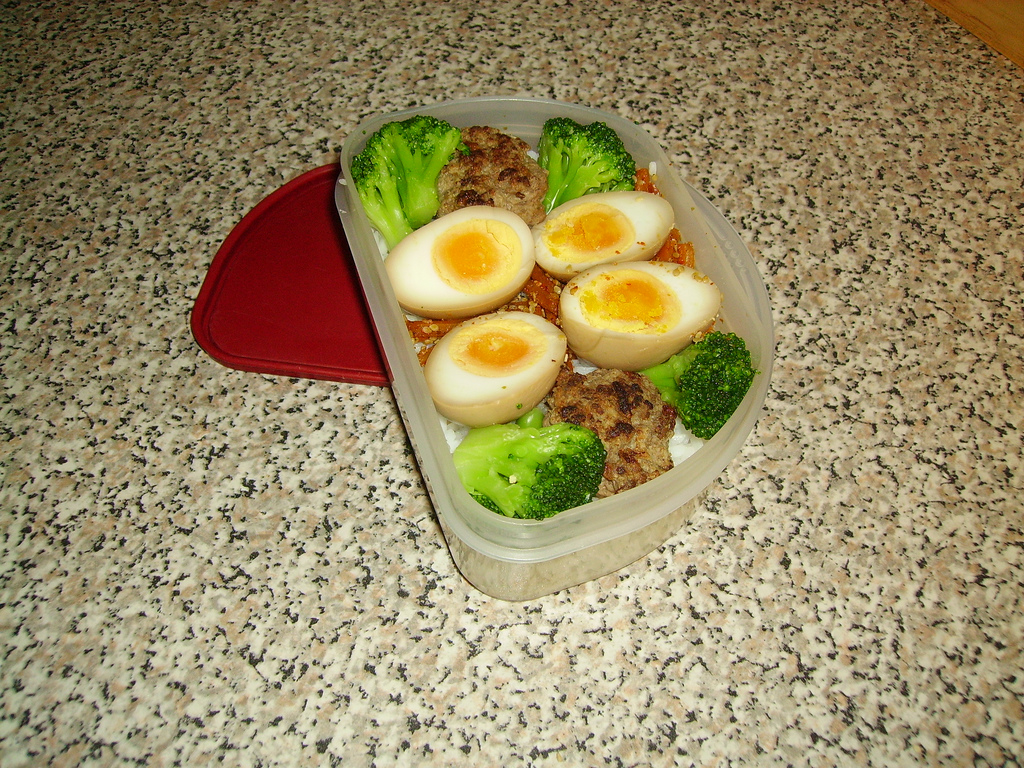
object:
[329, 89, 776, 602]
plastic container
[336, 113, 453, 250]
broccoli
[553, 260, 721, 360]
egg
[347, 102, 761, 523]
food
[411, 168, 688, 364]
potato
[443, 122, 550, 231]
steak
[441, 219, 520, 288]
yellow part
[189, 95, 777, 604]
container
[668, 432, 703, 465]
rice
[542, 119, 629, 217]
broccoli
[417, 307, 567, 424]
egg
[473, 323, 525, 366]
yolk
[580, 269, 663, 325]
york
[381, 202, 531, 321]
egg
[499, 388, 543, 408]
shell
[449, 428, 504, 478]
stem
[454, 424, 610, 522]
broccoli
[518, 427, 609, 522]
bush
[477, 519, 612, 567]
tupperware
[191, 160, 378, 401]
lid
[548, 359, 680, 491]
meat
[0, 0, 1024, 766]
counter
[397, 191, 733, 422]
eggs